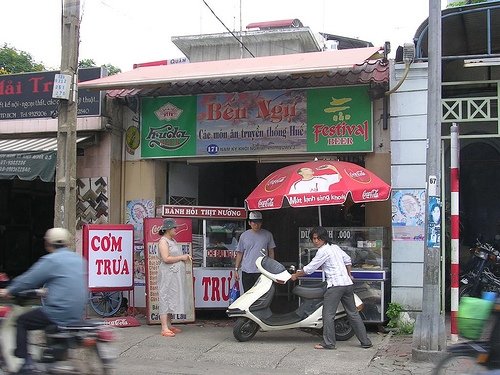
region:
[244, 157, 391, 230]
A red sun umbrella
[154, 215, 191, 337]
A lady wearing a hat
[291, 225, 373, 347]
A person in a white shirt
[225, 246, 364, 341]
A white scooter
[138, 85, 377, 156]
An advertising sign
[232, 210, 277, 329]
A man in a grey shirt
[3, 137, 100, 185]
Part of an awning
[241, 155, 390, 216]
A Coca Cola sun umbrella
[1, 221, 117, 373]
A man riding a scooter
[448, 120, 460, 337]
A red and white striped pole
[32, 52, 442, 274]
a business with customers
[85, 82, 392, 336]
these people are in front of a store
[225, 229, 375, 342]
this man has a white scooter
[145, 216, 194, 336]
this lady is lookng at the man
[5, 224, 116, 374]
this man is riding a scooter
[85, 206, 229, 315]
advertisements for the restuarant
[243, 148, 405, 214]
a red umbrella with ads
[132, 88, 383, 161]
the store's front sign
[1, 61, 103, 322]
this is another business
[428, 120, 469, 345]
a red and white pole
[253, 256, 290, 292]
the scooter is sitting on the sidewalk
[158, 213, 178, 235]
the hat is gray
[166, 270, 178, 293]
the dress ia light gray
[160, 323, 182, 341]
the shoes are orange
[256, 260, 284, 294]
the scooter is gray and white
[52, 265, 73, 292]
the shirt is blue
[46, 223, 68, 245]
the hat is white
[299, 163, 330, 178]
the man is drinking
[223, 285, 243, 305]
the bag is blue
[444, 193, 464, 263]
the pole is red and white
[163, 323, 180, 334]
woman wearing red sandles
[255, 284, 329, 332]
moped bike parked on pavement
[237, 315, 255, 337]
tire on the bike is black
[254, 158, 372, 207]
umbrella is over the stand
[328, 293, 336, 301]
man is wearing grey pants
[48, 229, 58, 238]
man wearing a tan hat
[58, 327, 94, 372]
man sitting on a bike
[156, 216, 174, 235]
woman wearing a grey hat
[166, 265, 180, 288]
woman wearing a long dress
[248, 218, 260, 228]
man is wearing eye glasses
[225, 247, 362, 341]
the moped in front of the building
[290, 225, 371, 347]
the man standing in front of the moped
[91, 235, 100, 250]
the letter "C" on the sign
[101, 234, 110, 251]
the letter "O" on the sign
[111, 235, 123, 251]
the letter "M" on the sign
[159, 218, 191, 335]
the woman standing on the sidewalk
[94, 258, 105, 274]
the letter "T" on the sign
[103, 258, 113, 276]
the letter "R" on the sign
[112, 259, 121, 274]
the letter "U" on the sign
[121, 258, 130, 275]
the letter "A" on the sign